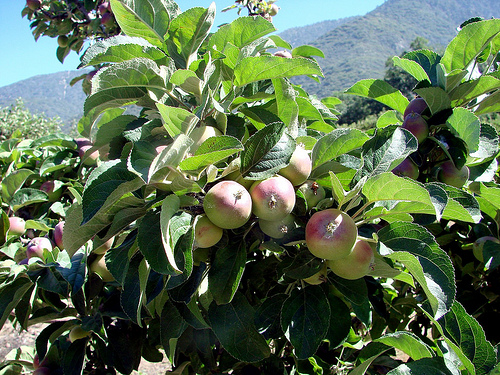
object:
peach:
[296, 180, 326, 209]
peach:
[328, 237, 375, 281]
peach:
[279, 146, 312, 186]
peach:
[473, 236, 500, 262]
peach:
[203, 181, 253, 230]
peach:
[55, 220, 65, 250]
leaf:
[232, 55, 325, 90]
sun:
[173, 5, 497, 288]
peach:
[306, 208, 358, 260]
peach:
[249, 174, 296, 221]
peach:
[259, 213, 296, 239]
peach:
[79, 144, 99, 165]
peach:
[27, 237, 55, 261]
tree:
[0, 94, 62, 141]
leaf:
[76, 35, 166, 70]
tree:
[0, 0, 499, 375]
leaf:
[208, 293, 271, 364]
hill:
[4, 1, 404, 132]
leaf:
[80, 161, 146, 225]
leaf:
[280, 285, 332, 360]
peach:
[438, 162, 470, 188]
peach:
[303, 260, 329, 285]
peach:
[227, 171, 255, 189]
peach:
[194, 216, 223, 248]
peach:
[187, 125, 223, 154]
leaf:
[371, 222, 456, 322]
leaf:
[417, 298, 495, 374]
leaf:
[324, 294, 352, 350]